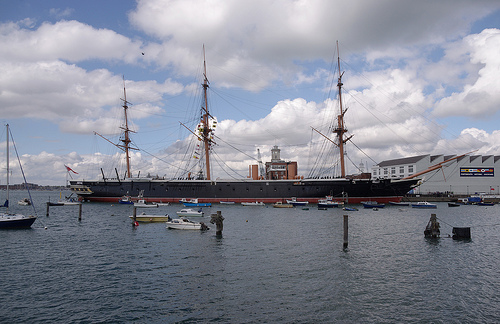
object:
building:
[375, 152, 500, 196]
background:
[1, 0, 500, 146]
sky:
[0, 0, 499, 102]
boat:
[166, 217, 202, 229]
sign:
[460, 168, 495, 175]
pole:
[344, 216, 351, 251]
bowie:
[135, 222, 141, 229]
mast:
[334, 39, 351, 178]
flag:
[194, 107, 204, 162]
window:
[218, 186, 222, 190]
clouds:
[132, 3, 497, 67]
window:
[408, 164, 413, 176]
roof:
[379, 154, 431, 166]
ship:
[68, 41, 481, 201]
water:
[6, 251, 499, 323]